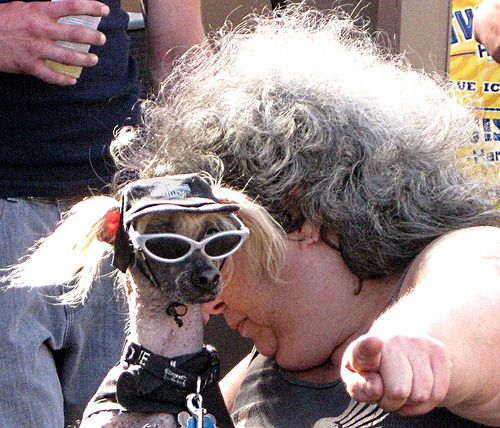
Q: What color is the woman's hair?
A: Gray.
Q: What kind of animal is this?
A: A dog.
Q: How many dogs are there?
A: One.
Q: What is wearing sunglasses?
A: The dog.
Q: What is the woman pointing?
A: Her finger.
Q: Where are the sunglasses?
A: On the dog.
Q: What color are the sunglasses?
A: White.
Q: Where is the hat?
A: On the dog's head.